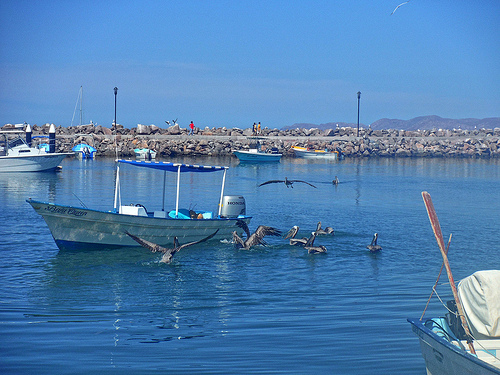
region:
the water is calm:
[93, 288, 165, 335]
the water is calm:
[256, 294, 355, 339]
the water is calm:
[374, 202, 403, 233]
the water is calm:
[332, 196, 397, 211]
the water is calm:
[187, 282, 274, 338]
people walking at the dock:
[172, 114, 274, 145]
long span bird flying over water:
[250, 173, 322, 200]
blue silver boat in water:
[25, 135, 257, 260]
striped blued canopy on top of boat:
[104, 151, 233, 217]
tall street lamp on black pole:
[107, 84, 125, 124]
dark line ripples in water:
[132, 305, 214, 350]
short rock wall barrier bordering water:
[8, 133, 497, 168]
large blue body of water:
[1, 145, 497, 374]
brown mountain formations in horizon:
[298, 110, 497, 130]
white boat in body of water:
[2, 126, 76, 179]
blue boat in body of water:
[230, 142, 287, 167]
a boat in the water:
[19, 139, 266, 272]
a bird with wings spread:
[120, 222, 219, 274]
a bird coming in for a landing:
[252, 167, 319, 207]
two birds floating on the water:
[285, 222, 329, 265]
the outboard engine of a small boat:
[212, 184, 260, 226]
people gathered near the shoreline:
[83, 109, 370, 144]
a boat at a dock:
[6, 133, 73, 186]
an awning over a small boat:
[105, 152, 244, 217]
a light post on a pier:
[93, 79, 132, 156]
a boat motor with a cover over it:
[443, 262, 496, 346]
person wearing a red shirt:
[186, 118, 198, 134]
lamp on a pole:
[354, 83, 366, 138]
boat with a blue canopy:
[18, 156, 261, 246]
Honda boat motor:
[216, 193, 251, 221]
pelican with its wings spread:
[120, 225, 225, 267]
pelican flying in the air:
[252, 172, 322, 197]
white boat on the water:
[0, 130, 81, 181]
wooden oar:
[420, 182, 475, 367]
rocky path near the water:
[0, 108, 499, 159]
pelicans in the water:
[279, 215, 388, 262]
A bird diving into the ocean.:
[122, 227, 223, 267]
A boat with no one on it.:
[20, 152, 256, 246]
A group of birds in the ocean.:
[224, 219, 397, 262]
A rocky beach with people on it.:
[70, 83, 420, 164]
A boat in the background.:
[233, 135, 284, 163]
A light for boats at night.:
[350, 86, 369, 110]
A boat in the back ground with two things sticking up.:
[4, 119, 75, 179]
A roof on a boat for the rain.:
[112, 147, 234, 186]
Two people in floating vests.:
[247, 119, 269, 139]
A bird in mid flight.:
[249, 164, 323, 199]